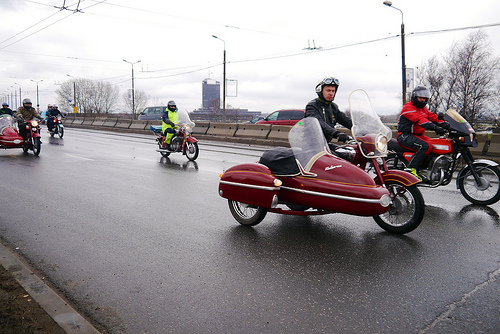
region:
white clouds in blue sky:
[41, 16, 65, 40]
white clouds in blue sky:
[116, 18, 149, 37]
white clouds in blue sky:
[124, 31, 177, 67]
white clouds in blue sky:
[233, 18, 273, 60]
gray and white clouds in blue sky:
[145, 50, 195, 85]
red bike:
[133, 93, 204, 168]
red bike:
[202, 71, 412, 229]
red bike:
[386, 72, 473, 157]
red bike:
[2, 96, 50, 180]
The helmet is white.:
[309, 73, 337, 89]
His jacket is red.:
[388, 89, 441, 142]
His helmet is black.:
[400, 81, 432, 109]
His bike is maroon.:
[222, 75, 432, 247]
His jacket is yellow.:
[146, 109, 178, 136]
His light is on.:
[25, 119, 42, 129]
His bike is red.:
[386, 121, 496, 212]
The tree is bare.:
[54, 77, 126, 110]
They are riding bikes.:
[16, 80, 498, 244]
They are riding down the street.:
[2, 63, 497, 259]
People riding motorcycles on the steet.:
[104, 85, 435, 216]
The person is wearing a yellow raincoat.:
[154, 102, 183, 134]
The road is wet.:
[77, 168, 242, 300]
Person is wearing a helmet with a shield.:
[402, 78, 434, 113]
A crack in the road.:
[416, 247, 485, 324]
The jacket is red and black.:
[382, 96, 442, 137]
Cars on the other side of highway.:
[135, 93, 301, 128]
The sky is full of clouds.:
[98, 18, 443, 74]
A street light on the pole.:
[378, 1, 420, 129]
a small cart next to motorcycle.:
[219, 141, 403, 236]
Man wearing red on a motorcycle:
[155, 97, 200, 166]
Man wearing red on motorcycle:
[397, 84, 497, 198]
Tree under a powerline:
[425, 13, 498, 121]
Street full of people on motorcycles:
[1, 85, 496, 332]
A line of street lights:
[70, 1, 449, 85]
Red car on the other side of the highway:
[247, 102, 305, 127]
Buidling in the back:
[196, 75, 260, 124]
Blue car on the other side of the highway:
[138, 102, 164, 121]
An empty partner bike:
[223, 118, 423, 240]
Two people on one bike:
[42, 103, 64, 141]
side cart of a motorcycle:
[222, 110, 368, 227]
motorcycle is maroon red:
[233, 143, 403, 216]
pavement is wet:
[84, 115, 404, 310]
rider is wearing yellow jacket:
[155, 111, 192, 153]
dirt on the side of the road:
[6, 263, 98, 320]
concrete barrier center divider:
[63, 105, 311, 147]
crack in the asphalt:
[364, 270, 489, 330]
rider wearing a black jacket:
[298, 92, 347, 152]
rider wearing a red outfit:
[406, 103, 440, 171]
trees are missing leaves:
[55, 75, 159, 132]